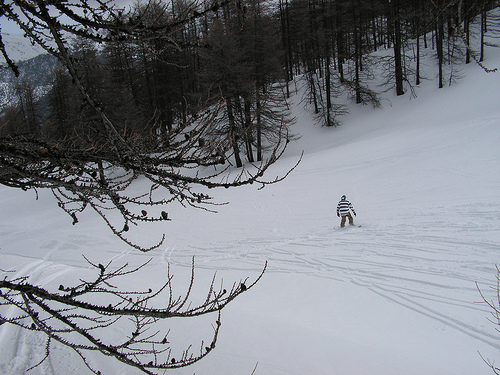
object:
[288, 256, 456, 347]
snow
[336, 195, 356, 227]
man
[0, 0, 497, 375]
hill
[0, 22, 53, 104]
snow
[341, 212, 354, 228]
pants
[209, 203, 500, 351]
tracks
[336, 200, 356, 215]
shirt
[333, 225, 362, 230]
snowboard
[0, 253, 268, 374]
branch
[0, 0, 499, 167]
trees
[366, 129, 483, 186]
snow